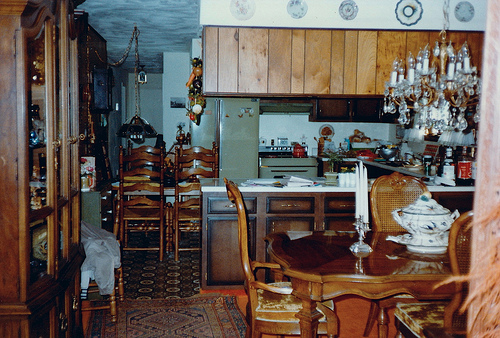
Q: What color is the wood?
A: Brown.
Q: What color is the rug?
A: Red and black.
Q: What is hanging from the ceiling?
A: The chandelier.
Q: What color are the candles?
A: White.